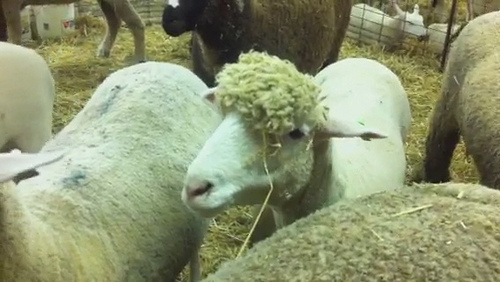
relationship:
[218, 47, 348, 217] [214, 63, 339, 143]
white wooly sheep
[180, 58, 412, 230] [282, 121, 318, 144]
sheep left eye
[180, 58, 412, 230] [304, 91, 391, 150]
sheep left ear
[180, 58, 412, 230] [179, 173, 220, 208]
sheep pink nose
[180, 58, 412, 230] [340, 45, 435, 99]
sheep rear end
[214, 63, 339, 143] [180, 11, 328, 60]
sheep that black and brown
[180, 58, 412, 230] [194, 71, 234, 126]
sheep right ear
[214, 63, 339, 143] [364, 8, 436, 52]
sheep laying in grass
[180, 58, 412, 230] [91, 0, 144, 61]
sheep rear bottom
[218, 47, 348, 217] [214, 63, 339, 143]
head of sheep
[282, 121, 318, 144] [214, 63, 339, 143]
eye of sheep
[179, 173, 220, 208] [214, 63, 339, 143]
nose of sheep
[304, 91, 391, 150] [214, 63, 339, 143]
ear of sheep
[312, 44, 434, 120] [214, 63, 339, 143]
back of sheep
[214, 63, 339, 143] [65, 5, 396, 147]
sheep in pen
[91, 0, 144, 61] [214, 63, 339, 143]
bottom of sheep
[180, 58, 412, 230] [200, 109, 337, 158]
sheep of head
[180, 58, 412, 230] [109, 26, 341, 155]
sheep side by side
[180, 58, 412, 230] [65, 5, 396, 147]
sheep standing in hay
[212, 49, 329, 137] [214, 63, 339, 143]
haircut white sheep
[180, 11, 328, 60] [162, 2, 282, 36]
unsheared brown animal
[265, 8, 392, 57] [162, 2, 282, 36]
rear portion animal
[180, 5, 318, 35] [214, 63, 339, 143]
unsheared brown sheep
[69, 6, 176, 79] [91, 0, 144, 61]
bottom of bottom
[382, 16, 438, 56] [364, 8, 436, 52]
metal fence encaging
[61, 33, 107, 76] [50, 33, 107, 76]
hay and hay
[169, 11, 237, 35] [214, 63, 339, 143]
black nose sheep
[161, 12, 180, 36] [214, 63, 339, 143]
black nose under sheep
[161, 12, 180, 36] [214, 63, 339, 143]
black nose of sheep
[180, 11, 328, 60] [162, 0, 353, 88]
black and brown nose animal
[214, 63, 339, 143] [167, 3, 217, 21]
sheep has black eyes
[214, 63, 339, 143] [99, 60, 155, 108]
sheep has dirt back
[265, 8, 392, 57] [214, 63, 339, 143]
behind of sheep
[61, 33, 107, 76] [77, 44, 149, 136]
hay on ground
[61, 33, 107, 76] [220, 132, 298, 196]
hay on sheeps face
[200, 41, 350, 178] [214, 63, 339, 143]
haircut on sheep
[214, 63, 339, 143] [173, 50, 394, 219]
sheep on head